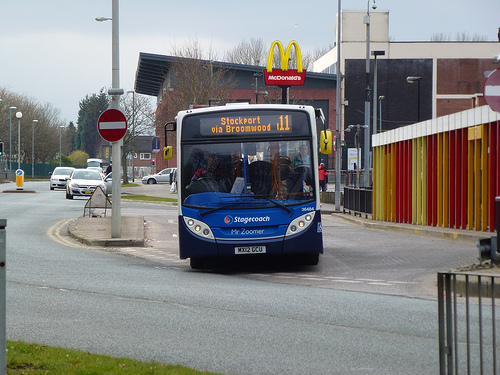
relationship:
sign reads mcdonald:
[261, 37, 313, 90] [267, 73, 302, 82]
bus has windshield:
[169, 101, 330, 272] [186, 139, 318, 210]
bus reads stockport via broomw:
[169, 101, 330, 272] [207, 114, 272, 135]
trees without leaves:
[5, 96, 68, 156] [82, 98, 95, 105]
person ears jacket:
[319, 161, 331, 193] [315, 167, 331, 183]